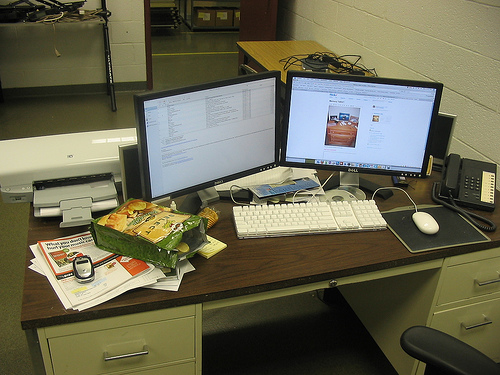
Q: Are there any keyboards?
A: Yes, there is a keyboard.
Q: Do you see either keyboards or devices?
A: Yes, there is a keyboard.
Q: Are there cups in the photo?
A: No, there are no cups.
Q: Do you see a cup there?
A: No, there are no cups.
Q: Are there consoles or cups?
A: No, there are no cups or consoles.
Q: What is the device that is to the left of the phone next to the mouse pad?
A: The device is a keyboard.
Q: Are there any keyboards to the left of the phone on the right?
A: Yes, there is a keyboard to the left of the phone.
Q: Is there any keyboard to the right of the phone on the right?
A: No, the keyboard is to the left of the phone.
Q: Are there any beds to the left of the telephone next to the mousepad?
A: No, there is a keyboard to the left of the telephone.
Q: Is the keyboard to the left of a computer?
A: No, the keyboard is to the left of the phone.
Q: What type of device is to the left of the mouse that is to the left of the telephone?
A: The device is a keyboard.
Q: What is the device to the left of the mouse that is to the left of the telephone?
A: The device is a keyboard.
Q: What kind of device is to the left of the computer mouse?
A: The device is a keyboard.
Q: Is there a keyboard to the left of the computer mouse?
A: Yes, there is a keyboard to the left of the computer mouse.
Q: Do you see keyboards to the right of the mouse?
A: No, the keyboard is to the left of the mouse.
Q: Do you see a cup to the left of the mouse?
A: No, there is a keyboard to the left of the mouse.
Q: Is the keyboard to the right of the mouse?
A: No, the keyboard is to the left of the mouse.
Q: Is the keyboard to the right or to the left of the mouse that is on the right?
A: The keyboard is to the left of the computer mouse.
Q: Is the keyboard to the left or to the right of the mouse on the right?
A: The keyboard is to the left of the computer mouse.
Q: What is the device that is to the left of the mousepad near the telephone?
A: The device is a keyboard.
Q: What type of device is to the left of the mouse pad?
A: The device is a keyboard.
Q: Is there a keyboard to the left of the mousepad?
A: Yes, there is a keyboard to the left of the mousepad.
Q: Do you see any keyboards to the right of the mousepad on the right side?
A: No, the keyboard is to the left of the mouse pad.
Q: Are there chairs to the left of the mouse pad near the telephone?
A: No, there is a keyboard to the left of the mousepad.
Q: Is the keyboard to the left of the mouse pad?
A: Yes, the keyboard is to the left of the mouse pad.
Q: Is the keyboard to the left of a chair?
A: No, the keyboard is to the left of the mouse pad.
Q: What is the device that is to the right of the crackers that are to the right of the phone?
A: The device is a keyboard.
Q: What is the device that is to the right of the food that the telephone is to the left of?
A: The device is a keyboard.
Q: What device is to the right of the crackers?
A: The device is a keyboard.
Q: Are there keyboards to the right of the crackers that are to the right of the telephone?
A: Yes, there is a keyboard to the right of the crackers.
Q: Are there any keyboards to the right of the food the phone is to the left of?
A: Yes, there is a keyboard to the right of the crackers.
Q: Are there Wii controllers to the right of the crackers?
A: No, there is a keyboard to the right of the crackers.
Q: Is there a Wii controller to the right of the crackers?
A: No, there is a keyboard to the right of the crackers.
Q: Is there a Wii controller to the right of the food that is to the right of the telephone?
A: No, there is a keyboard to the right of the crackers.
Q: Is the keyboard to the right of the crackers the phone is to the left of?
A: Yes, the keyboard is to the right of the crackers.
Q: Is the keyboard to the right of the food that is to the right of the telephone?
A: Yes, the keyboard is to the right of the crackers.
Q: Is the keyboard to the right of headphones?
A: No, the keyboard is to the right of the crackers.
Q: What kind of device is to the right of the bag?
A: The device is a keyboard.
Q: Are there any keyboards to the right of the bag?
A: Yes, there is a keyboard to the right of the bag.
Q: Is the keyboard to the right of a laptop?
A: No, the keyboard is to the right of the bag.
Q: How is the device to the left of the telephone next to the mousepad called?
A: The device is a monitor.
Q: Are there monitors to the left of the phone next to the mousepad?
A: Yes, there is a monitor to the left of the phone.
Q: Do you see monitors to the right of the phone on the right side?
A: No, the monitor is to the left of the telephone.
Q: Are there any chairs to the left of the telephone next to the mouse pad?
A: No, there is a monitor to the left of the phone.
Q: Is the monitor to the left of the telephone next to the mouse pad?
A: Yes, the monitor is to the left of the phone.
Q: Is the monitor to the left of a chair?
A: No, the monitor is to the left of the phone.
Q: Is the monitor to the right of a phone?
A: No, the monitor is to the left of a phone.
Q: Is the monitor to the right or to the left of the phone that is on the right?
A: The monitor is to the left of the telephone.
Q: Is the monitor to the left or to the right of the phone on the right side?
A: The monitor is to the left of the telephone.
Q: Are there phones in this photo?
A: Yes, there is a phone.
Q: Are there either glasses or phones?
A: Yes, there is a phone.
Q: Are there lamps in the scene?
A: No, there are no lamps.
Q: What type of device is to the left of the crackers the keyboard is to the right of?
A: The device is a phone.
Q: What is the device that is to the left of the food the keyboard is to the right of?
A: The device is a phone.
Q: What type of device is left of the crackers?
A: The device is a phone.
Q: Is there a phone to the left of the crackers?
A: Yes, there is a phone to the left of the crackers.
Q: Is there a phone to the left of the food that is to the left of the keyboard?
A: Yes, there is a phone to the left of the crackers.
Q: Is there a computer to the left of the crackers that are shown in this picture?
A: No, there is a phone to the left of the crackers.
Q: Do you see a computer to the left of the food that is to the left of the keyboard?
A: No, there is a phone to the left of the crackers.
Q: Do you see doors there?
A: Yes, there is a door.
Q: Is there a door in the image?
A: Yes, there is a door.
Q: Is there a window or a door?
A: Yes, there is a door.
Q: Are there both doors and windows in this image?
A: No, there is a door but no windows.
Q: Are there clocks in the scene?
A: No, there are no clocks.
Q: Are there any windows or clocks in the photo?
A: No, there are no clocks or windows.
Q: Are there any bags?
A: Yes, there is a bag.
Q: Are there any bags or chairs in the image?
A: Yes, there is a bag.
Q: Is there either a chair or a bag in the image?
A: Yes, there is a bag.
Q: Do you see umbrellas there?
A: No, there are no umbrellas.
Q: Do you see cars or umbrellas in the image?
A: No, there are no umbrellas or cars.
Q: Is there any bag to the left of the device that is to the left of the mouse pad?
A: Yes, there is a bag to the left of the keyboard.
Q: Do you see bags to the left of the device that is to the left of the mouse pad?
A: Yes, there is a bag to the left of the keyboard.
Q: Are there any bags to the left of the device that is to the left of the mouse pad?
A: Yes, there is a bag to the left of the keyboard.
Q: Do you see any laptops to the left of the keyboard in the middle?
A: No, there is a bag to the left of the keyboard.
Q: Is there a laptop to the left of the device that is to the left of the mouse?
A: No, there is a bag to the left of the keyboard.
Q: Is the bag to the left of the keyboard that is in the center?
A: Yes, the bag is to the left of the keyboard.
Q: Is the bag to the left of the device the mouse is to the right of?
A: Yes, the bag is to the left of the keyboard.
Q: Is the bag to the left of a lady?
A: No, the bag is to the left of the keyboard.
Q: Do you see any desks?
A: Yes, there is a desk.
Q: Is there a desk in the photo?
A: Yes, there is a desk.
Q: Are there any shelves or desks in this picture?
A: Yes, there is a desk.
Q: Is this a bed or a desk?
A: This is a desk.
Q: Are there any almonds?
A: No, there are no almonds.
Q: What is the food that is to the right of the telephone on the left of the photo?
A: The food is crackers.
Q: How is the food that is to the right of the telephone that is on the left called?
A: The food is crackers.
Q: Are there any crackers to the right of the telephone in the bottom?
A: Yes, there are crackers to the right of the phone.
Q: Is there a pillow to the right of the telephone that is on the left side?
A: No, there are crackers to the right of the phone.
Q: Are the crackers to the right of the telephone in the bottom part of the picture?
A: Yes, the crackers are to the right of the telephone.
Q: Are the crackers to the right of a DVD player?
A: No, the crackers are to the right of the telephone.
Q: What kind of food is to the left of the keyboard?
A: The food is crackers.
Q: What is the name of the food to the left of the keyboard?
A: The food is crackers.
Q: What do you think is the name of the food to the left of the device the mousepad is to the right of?
A: The food is crackers.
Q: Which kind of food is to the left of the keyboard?
A: The food is crackers.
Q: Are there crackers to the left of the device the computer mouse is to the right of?
A: Yes, there are crackers to the left of the keyboard.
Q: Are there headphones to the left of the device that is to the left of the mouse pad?
A: No, there are crackers to the left of the keyboard.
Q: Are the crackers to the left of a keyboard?
A: Yes, the crackers are to the left of a keyboard.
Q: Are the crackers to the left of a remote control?
A: No, the crackers are to the left of a keyboard.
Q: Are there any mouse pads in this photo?
A: Yes, there is a mouse pad.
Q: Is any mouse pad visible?
A: Yes, there is a mouse pad.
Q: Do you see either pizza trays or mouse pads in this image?
A: Yes, there is a mouse pad.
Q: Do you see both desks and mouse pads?
A: Yes, there are both a mouse pad and a desk.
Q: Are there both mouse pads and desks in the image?
A: Yes, there are both a mouse pad and a desk.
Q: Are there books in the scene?
A: No, there are no books.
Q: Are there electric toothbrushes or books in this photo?
A: No, there are no books or electric toothbrushes.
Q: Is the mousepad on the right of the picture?
A: Yes, the mousepad is on the right of the image.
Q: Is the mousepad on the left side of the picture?
A: No, the mousepad is on the right of the image.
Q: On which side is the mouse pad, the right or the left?
A: The mouse pad is on the right of the image.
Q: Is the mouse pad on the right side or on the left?
A: The mouse pad is on the right of the image.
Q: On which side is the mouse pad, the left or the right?
A: The mouse pad is on the right of the image.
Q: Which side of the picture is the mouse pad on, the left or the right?
A: The mouse pad is on the right of the image.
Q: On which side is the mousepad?
A: The mousepad is on the right of the image.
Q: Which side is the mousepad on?
A: The mousepad is on the right of the image.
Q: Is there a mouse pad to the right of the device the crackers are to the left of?
A: Yes, there is a mouse pad to the right of the keyboard.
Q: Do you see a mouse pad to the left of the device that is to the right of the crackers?
A: No, the mouse pad is to the right of the keyboard.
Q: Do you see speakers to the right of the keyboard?
A: No, there is a mouse pad to the right of the keyboard.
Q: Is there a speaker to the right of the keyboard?
A: No, there is a mouse pad to the right of the keyboard.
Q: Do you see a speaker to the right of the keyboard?
A: No, there is a mouse pad to the right of the keyboard.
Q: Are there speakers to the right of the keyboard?
A: No, there is a mouse pad to the right of the keyboard.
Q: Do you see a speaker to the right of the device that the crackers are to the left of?
A: No, there is a mouse pad to the right of the keyboard.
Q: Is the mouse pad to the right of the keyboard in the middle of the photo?
A: Yes, the mouse pad is to the right of the keyboard.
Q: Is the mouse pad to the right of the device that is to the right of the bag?
A: Yes, the mouse pad is to the right of the keyboard.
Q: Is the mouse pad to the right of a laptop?
A: No, the mouse pad is to the right of the keyboard.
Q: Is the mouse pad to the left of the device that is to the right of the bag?
A: No, the mouse pad is to the right of the keyboard.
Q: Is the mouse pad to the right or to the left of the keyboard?
A: The mouse pad is to the right of the keyboard.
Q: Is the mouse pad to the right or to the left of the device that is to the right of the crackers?
A: The mouse pad is to the right of the keyboard.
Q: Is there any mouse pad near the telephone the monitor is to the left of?
A: Yes, there is a mouse pad near the phone.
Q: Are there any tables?
A: Yes, there is a table.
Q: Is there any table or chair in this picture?
A: Yes, there is a table.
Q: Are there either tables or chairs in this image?
A: Yes, there is a table.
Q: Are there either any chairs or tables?
A: Yes, there is a table.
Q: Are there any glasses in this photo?
A: No, there are no glasses.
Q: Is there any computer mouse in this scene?
A: Yes, there is a computer mouse.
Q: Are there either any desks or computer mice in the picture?
A: Yes, there is a computer mouse.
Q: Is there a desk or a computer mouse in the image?
A: Yes, there is a computer mouse.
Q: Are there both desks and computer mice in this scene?
A: Yes, there are both a computer mouse and a desk.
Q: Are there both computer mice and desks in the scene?
A: Yes, there are both a computer mouse and a desk.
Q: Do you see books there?
A: No, there are no books.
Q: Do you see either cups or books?
A: No, there are no books or cups.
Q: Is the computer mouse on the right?
A: Yes, the computer mouse is on the right of the image.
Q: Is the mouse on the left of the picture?
A: No, the mouse is on the right of the image.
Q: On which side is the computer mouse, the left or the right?
A: The computer mouse is on the right of the image.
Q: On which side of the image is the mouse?
A: The mouse is on the right of the image.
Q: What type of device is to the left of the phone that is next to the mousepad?
A: The device is a computer mouse.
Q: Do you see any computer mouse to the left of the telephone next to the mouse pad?
A: Yes, there is a computer mouse to the left of the phone.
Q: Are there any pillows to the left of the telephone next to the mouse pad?
A: No, there is a computer mouse to the left of the telephone.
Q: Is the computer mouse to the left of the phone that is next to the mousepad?
A: Yes, the computer mouse is to the left of the telephone.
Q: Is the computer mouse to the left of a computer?
A: No, the computer mouse is to the left of the telephone.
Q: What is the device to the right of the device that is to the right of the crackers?
A: The device is a computer mouse.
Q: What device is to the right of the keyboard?
A: The device is a computer mouse.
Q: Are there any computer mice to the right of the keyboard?
A: Yes, there is a computer mouse to the right of the keyboard.